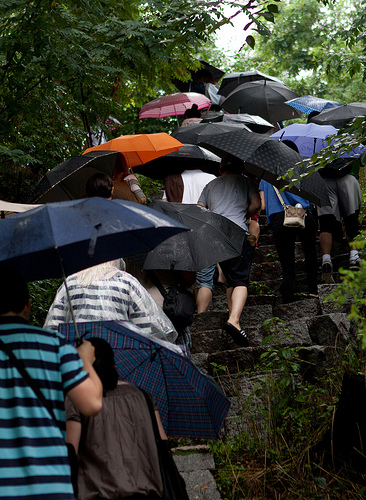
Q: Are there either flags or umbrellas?
A: Yes, there is an umbrella.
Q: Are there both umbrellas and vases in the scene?
A: No, there is an umbrella but no vases.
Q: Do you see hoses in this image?
A: No, there are no hoses.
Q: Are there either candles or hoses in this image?
A: No, there are no hoses or candles.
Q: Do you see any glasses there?
A: No, there are no glasses.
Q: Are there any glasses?
A: No, there are no glasses.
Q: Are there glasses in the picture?
A: No, there are no glasses.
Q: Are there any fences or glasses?
A: No, there are no glasses or fences.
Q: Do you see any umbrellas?
A: Yes, there is an umbrella.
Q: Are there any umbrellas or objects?
A: Yes, there is an umbrella.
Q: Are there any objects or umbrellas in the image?
A: Yes, there is an umbrella.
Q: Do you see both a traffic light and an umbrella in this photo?
A: No, there is an umbrella but no traffic lights.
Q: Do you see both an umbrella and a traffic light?
A: No, there is an umbrella but no traffic lights.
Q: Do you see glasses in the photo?
A: No, there are no glasses.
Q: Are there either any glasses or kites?
A: No, there are no glasses or kites.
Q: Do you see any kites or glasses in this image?
A: No, there are no glasses or kites.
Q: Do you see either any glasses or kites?
A: No, there are no glasses or kites.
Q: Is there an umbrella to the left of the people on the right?
A: Yes, there is an umbrella to the left of the people.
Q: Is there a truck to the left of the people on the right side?
A: No, there is an umbrella to the left of the people.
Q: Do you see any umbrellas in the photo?
A: Yes, there is an umbrella.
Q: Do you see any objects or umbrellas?
A: Yes, there is an umbrella.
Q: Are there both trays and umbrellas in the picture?
A: No, there is an umbrella but no trays.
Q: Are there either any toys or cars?
A: No, there are no cars or toys.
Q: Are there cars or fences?
A: No, there are no cars or fences.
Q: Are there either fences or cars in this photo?
A: No, there are no cars or fences.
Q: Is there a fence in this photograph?
A: No, there are no fences.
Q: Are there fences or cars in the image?
A: No, there are no fences or cars.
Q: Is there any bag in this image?
A: Yes, there is a bag.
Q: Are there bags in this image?
A: Yes, there is a bag.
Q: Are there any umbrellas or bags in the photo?
A: Yes, there is a bag.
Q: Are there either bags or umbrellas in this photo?
A: Yes, there is a bag.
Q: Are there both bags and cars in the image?
A: No, there is a bag but no cars.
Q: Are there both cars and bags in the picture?
A: No, there is a bag but no cars.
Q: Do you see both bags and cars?
A: No, there is a bag but no cars.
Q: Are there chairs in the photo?
A: No, there are no chairs.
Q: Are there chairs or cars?
A: No, there are no chairs or cars.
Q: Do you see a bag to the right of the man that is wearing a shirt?
A: Yes, there is a bag to the right of the man.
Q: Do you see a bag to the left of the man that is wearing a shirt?
A: No, the bag is to the right of the man.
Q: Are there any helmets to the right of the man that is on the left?
A: No, there is a bag to the right of the man.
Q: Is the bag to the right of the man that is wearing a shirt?
A: Yes, the bag is to the right of the man.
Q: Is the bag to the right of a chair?
A: No, the bag is to the right of the man.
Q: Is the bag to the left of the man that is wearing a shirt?
A: No, the bag is to the right of the man.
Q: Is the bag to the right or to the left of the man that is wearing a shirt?
A: The bag is to the right of the man.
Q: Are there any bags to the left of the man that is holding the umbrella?
A: Yes, there is a bag to the left of the man.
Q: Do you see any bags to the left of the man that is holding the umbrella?
A: Yes, there is a bag to the left of the man.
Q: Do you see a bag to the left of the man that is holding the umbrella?
A: Yes, there is a bag to the left of the man.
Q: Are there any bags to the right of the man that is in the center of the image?
A: No, the bag is to the left of the man.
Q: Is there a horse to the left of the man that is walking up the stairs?
A: No, there is a bag to the left of the man.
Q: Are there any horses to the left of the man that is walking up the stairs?
A: No, there is a bag to the left of the man.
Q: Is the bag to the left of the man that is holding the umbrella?
A: Yes, the bag is to the left of the man.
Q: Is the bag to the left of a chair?
A: No, the bag is to the left of the man.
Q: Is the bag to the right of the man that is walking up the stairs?
A: No, the bag is to the left of the man.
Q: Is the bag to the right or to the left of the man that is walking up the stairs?
A: The bag is to the left of the man.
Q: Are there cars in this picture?
A: No, there are no cars.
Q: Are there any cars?
A: No, there are no cars.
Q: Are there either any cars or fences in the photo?
A: No, there are no cars or fences.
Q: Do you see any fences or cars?
A: No, there are no cars or fences.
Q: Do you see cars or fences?
A: No, there are no cars or fences.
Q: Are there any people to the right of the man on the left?
A: Yes, there is a person to the right of the man.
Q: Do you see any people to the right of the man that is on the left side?
A: Yes, there is a person to the right of the man.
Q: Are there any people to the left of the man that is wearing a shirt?
A: No, the person is to the right of the man.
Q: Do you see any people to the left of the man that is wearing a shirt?
A: No, the person is to the right of the man.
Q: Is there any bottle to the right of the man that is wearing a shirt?
A: No, there is a person to the right of the man.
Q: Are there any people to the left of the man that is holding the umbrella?
A: Yes, there is a person to the left of the man.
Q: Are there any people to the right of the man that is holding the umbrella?
A: No, the person is to the left of the man.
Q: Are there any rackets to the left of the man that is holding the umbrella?
A: No, there is a person to the left of the man.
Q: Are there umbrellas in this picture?
A: Yes, there is an umbrella.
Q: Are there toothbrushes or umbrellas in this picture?
A: Yes, there is an umbrella.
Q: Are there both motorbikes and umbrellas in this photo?
A: No, there is an umbrella but no motorcycles.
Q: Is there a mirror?
A: No, there are no mirrors.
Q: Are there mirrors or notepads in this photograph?
A: No, there are no mirrors or notepads.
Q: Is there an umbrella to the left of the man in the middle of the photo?
A: Yes, there is an umbrella to the left of the man.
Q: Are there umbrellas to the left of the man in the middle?
A: Yes, there is an umbrella to the left of the man.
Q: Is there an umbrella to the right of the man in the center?
A: No, the umbrella is to the left of the man.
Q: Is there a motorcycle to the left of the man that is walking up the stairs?
A: No, there is an umbrella to the left of the man.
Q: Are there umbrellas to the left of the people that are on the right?
A: Yes, there is an umbrella to the left of the people.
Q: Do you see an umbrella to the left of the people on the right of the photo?
A: Yes, there is an umbrella to the left of the people.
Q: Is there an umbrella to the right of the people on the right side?
A: No, the umbrella is to the left of the people.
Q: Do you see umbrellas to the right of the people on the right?
A: No, the umbrella is to the left of the people.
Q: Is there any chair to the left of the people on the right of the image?
A: No, there is an umbrella to the left of the people.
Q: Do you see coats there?
A: Yes, there is a coat.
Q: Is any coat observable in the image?
A: Yes, there is a coat.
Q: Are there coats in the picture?
A: Yes, there is a coat.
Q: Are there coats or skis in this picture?
A: Yes, there is a coat.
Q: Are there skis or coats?
A: Yes, there is a coat.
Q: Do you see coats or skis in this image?
A: Yes, there is a coat.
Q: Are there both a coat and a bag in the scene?
A: Yes, there are both a coat and a bag.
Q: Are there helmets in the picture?
A: No, there are no helmets.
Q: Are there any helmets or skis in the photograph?
A: No, there are no helmets or skis.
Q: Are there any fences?
A: No, there are no fences.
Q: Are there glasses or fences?
A: No, there are no fences or glasses.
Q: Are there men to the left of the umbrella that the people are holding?
A: Yes, there is a man to the left of the umbrella.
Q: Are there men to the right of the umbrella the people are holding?
A: No, the man is to the left of the umbrella.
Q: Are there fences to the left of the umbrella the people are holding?
A: No, there is a man to the left of the umbrella.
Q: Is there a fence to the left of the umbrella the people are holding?
A: No, there is a man to the left of the umbrella.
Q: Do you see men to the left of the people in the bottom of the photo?
A: Yes, there is a man to the left of the people.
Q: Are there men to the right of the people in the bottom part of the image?
A: No, the man is to the left of the people.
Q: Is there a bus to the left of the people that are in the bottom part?
A: No, there is a man to the left of the people.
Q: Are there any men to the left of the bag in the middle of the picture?
A: Yes, there is a man to the left of the bag.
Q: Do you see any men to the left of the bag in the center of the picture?
A: Yes, there is a man to the left of the bag.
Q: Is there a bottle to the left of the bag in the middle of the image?
A: No, there is a man to the left of the bag.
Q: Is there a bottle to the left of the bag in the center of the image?
A: No, there is a man to the left of the bag.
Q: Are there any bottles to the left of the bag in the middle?
A: No, there is a man to the left of the bag.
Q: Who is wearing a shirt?
A: The man is wearing a shirt.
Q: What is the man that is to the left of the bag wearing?
A: The man is wearing a shirt.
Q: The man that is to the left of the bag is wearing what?
A: The man is wearing a shirt.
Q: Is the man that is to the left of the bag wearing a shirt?
A: Yes, the man is wearing a shirt.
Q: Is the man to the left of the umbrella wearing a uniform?
A: No, the man is wearing a shirt.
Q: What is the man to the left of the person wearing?
A: The man is wearing a shirt.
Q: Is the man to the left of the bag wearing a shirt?
A: Yes, the man is wearing a shirt.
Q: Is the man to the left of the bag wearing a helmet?
A: No, the man is wearing a shirt.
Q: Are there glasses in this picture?
A: No, there are no glasses.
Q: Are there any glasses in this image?
A: No, there are no glasses.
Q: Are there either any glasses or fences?
A: No, there are no glasses or fences.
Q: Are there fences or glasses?
A: No, there are no glasses or fences.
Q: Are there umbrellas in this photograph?
A: Yes, there is an umbrella.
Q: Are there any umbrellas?
A: Yes, there is an umbrella.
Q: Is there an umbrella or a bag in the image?
A: Yes, there is an umbrella.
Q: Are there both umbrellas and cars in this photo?
A: No, there is an umbrella but no cars.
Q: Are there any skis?
A: No, there are no skis.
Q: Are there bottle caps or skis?
A: No, there are no skis or bottle caps.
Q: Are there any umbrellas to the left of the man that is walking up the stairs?
A: Yes, there is an umbrella to the left of the man.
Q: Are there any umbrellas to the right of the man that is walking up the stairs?
A: No, the umbrella is to the left of the man.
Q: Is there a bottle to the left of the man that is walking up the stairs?
A: No, there is an umbrella to the left of the man.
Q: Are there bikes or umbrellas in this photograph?
A: Yes, there is an umbrella.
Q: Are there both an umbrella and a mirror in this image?
A: No, there is an umbrella but no mirrors.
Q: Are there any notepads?
A: No, there are no notepads.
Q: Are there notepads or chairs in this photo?
A: No, there are no notepads or chairs.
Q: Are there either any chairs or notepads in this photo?
A: No, there are no notepads or chairs.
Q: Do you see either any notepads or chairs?
A: No, there are no notepads or chairs.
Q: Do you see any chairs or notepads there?
A: No, there are no notepads or chairs.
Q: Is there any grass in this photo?
A: Yes, there is grass.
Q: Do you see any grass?
A: Yes, there is grass.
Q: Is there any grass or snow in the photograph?
A: Yes, there is grass.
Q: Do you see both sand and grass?
A: No, there is grass but no sand.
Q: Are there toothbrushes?
A: No, there are no toothbrushes.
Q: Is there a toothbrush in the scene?
A: No, there are no toothbrushes.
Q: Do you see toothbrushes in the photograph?
A: No, there are no toothbrushes.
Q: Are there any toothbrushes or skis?
A: No, there are no toothbrushes or skis.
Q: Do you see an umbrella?
A: Yes, there is an umbrella.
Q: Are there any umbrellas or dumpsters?
A: Yes, there is an umbrella.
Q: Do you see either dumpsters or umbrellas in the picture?
A: Yes, there is an umbrella.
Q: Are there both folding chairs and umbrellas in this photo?
A: No, there is an umbrella but no folding chairs.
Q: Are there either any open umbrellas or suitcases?
A: Yes, there is an open umbrella.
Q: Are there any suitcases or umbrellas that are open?
A: Yes, the umbrella is open.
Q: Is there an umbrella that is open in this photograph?
A: Yes, there is an open umbrella.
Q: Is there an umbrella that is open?
A: Yes, there is an umbrella that is open.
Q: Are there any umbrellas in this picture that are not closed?
A: Yes, there is a open umbrella.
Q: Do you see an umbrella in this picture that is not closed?
A: Yes, there is a open umbrella.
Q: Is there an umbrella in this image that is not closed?
A: Yes, there is a open umbrella.